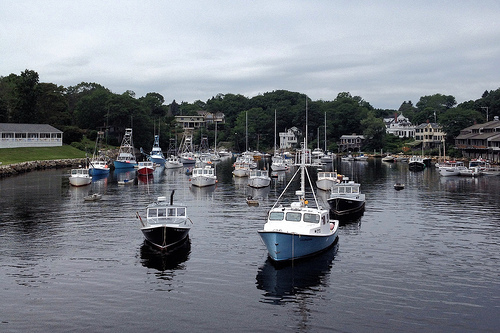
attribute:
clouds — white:
[0, 0, 498, 115]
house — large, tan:
[412, 120, 447, 158]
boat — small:
[135, 196, 196, 254]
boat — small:
[317, 176, 371, 221]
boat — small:
[181, 159, 216, 189]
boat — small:
[62, 158, 93, 190]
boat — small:
[430, 155, 482, 179]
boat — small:
[393, 177, 405, 189]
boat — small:
[136, 160, 153, 174]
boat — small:
[89, 191, 101, 200]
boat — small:
[245, 190, 260, 205]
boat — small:
[117, 177, 134, 186]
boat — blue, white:
[255, 139, 341, 262]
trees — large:
[1, 69, 498, 149]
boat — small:
[230, 147, 375, 294]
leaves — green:
[4, 72, 38, 94]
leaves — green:
[42, 91, 69, 107]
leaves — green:
[85, 97, 102, 111]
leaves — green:
[133, 101, 150, 116]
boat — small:
[128, 180, 212, 256]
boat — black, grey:
[131, 182, 198, 259]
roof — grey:
[0, 121, 63, 135]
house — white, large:
[388, 112, 448, 149]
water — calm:
[384, 205, 485, 319]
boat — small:
[135, 187, 195, 252]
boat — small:
[67, 158, 93, 185]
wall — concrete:
[0, 158, 70, 176]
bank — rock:
[4, 153, 91, 180]